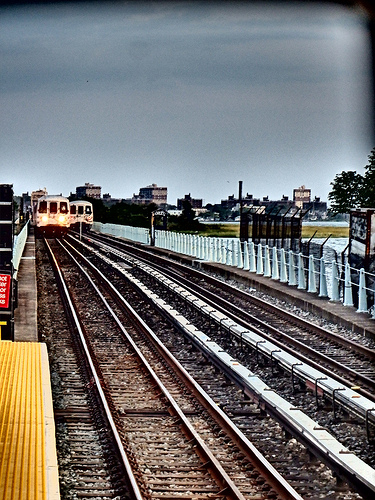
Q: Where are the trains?
A: On tracks.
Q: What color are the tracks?
A: Brown.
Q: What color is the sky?
A: Blue.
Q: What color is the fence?
A: White.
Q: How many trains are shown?
A: Two.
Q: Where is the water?
A: Beside fence.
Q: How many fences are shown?
A: One.